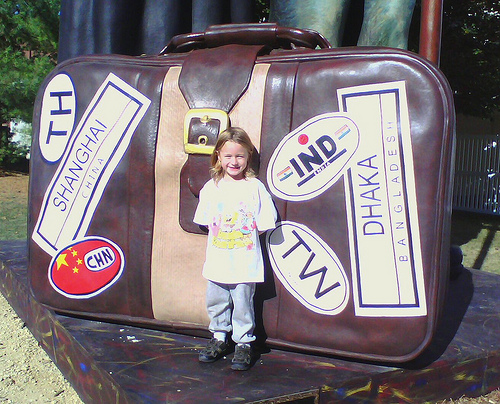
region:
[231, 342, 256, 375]
The girl's left shoe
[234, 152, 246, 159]
The girl's left eye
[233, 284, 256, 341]
The girl's left leg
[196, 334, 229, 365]
The girl's right shoe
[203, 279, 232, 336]
The girl's right leg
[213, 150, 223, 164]
The girl's right ear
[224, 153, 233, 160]
The girl's right eye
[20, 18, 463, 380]
enormous brown and green suitcase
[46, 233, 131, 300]
red and yellow sticker on the suitcase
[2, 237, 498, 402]
platform with red yellow and blue paint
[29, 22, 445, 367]
giant brown suitcase sculpture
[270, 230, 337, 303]
black lettering on white background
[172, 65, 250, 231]
strap of suitcase with gold buckle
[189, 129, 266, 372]
young girl standing in front of suitcase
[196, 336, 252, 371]
black shoes of young girl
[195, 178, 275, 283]
white shirt of young girl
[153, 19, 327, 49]
handle of brown suitcase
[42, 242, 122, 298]
red sticker with yellow stars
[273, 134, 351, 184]
navy blue lettering on white background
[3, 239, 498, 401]
base of suitcase sculpture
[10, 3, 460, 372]
Novelty suitcase outside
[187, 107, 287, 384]
Child standing in front of a suitcase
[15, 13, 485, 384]
Photo taken during the day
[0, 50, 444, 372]
The suitcase is brown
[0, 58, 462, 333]
Replica stickers on the suitcase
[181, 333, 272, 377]
Black shoes on the child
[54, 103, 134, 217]
SHANGHAI CHINA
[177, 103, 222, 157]
The buckle is gold colored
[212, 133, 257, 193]
The child is blond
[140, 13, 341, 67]
Handle of the suitcase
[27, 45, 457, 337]
Girl posing in front of large suitcase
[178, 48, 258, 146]
Brown strap with gold buckle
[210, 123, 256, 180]
Girl with blond hair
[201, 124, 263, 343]
Girl wearing gray sweat pants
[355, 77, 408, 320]
Luggage sticker for Dhaka Bangladesh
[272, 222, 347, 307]
Luggage sticker with letters TW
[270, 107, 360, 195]
Luggage sticker for India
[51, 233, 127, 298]
Luggage sticker for China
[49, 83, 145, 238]
Luggage sticker for Shanghai China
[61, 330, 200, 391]
Brown platform with colorful streaks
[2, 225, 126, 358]
sticker with yellow stars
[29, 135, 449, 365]
child standing next to large suitcase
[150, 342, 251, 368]
childs black tennis shoes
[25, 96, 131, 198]
two blue and white stickers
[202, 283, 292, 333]
cvhilds pair of sweat pants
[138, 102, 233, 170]
gold buckle on fake suitcase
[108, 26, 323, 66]
brown handle of a suitcase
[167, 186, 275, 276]
white shirt with disney cartoons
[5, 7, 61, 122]
green leaves with brown branches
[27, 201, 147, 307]
blue letters that say chn